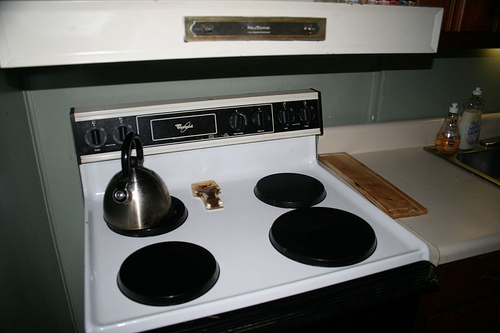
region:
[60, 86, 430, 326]
white and black stove next to counter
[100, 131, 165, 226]
silver tea kettle on stove top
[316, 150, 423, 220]
narrow wooden board on counter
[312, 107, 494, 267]
light colored counter next to stove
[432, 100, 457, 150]
plastic bottle orange soap on sink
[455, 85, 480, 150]
plastic bottle white soap on sink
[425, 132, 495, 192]
shiny silver sink next to counter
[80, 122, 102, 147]
black knob on stove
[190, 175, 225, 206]
ceramic decoration on stove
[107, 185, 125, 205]
black spout on kettle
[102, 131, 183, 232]
this is a kettle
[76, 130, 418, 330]
this is a gas cooker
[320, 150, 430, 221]
this is a chopping board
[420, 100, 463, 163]
this is a bottle of oil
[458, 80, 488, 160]
this is a bottle of lotion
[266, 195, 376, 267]
this is a cooker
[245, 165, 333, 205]
this is a cooker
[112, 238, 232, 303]
this is a cooker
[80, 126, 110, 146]
this is an ON button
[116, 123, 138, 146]
this is an ON button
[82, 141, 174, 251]
steel teakettle on stove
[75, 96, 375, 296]
black and white range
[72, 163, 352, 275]
black burners on range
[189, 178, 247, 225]
clear spoon holder on range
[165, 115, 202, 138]
white logo on range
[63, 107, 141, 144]
black knobs on range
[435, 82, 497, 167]
soap bottles on right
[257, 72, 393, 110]
green wall behind range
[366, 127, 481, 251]
grey countertop near sink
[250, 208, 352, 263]
circular burners on range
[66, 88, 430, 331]
white stove with black burner covers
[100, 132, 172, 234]
metal whistling tea kettle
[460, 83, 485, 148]
clear plastic squeeze bottle of white dish soap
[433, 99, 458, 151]
clear plastic squeeze bottle of orange dish soap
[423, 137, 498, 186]
stainless steel kitchen sink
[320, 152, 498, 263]
formica countertop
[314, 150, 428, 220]
narrow wood tray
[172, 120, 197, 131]
white Whirlpool logo on stove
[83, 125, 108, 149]
black dial for stove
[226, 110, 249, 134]
black dial for stove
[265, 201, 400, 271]
a large stovetop burner.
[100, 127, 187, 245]
a metal tea kettle on a stove.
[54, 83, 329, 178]
a control panel for a stove.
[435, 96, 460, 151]
a bottle of dish soap.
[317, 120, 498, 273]
a white kitchen counter.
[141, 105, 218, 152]
the name brand of a stove.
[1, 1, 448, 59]
a stove top ventilation.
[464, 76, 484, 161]
dish soap on a tray.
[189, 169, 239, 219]
an object on a stove.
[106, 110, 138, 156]
control knob for a stove.